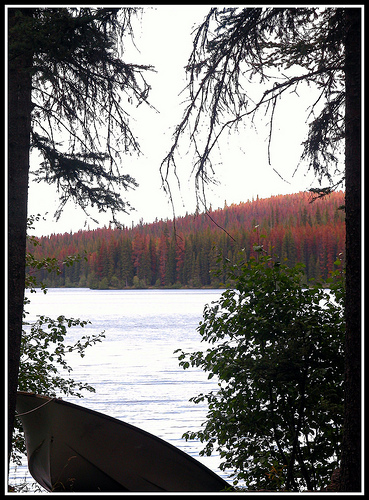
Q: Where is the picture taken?
A: A lake house.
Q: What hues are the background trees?
A: Reds.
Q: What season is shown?
A: Fall.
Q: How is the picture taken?
A: Through a window.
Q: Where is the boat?
A: On the lake.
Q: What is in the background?
A: A forest.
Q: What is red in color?
A: Trees.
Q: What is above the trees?
A: The sky.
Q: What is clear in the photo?
A: Water.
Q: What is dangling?
A: Branches.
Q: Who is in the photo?
A: No people.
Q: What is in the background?
A: Hills.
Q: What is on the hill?
A: Trees.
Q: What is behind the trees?
A: Sky.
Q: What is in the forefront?
A: A boat.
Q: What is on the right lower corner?
A: A green tree.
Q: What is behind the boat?
A: A river.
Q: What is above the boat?
A: Trees.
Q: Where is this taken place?
A: An ocean.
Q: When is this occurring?
A: During the day time.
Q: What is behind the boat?
A: Water.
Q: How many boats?
A: 1.